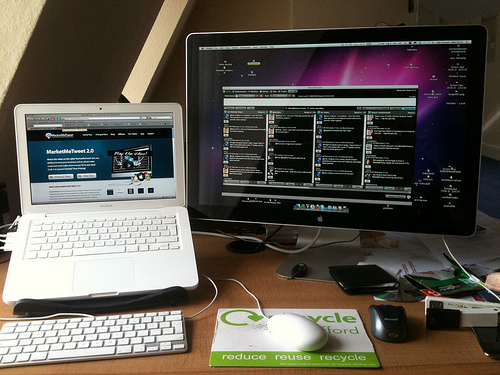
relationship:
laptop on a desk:
[1, 102, 198, 303] [0, 233, 495, 370]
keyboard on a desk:
[110, 217, 190, 257] [122, 264, 374, 364]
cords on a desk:
[189, 218, 324, 253] [9, 200, 485, 369]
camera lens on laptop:
[97, 105, 103, 110] [1, 102, 198, 303]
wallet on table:
[327, 266, 399, 296] [0, 210, 497, 373]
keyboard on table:
[5, 285, 212, 374] [1, 196, 484, 366]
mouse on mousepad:
[269, 302, 334, 354] [205, 298, 383, 368]